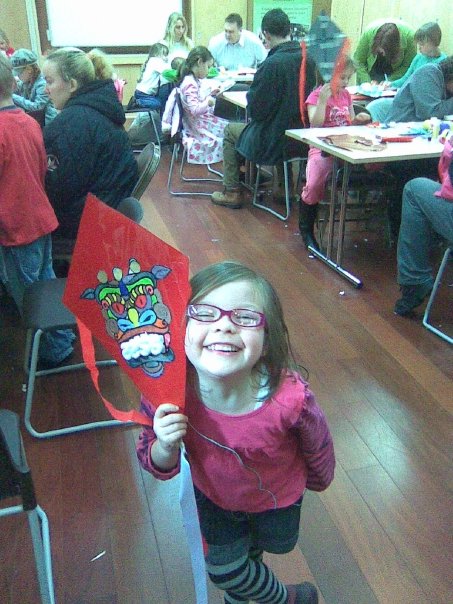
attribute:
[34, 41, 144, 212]
woman — in a black jacket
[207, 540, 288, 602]
girl — wearing striped pants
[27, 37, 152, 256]
person — sitting down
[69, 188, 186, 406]
kite — red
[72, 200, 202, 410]
kite — red, small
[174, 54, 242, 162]
girl — little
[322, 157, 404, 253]
girl — little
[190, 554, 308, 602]
leggings — striped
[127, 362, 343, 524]
shirt — pink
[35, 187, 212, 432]
kite — red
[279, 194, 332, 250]
boots — black, tall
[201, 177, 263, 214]
boot — brown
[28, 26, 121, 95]
hair — pony tail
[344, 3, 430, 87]
shirt — bright green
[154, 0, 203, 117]
hair — long, blonde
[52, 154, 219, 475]
kite — red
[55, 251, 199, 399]
face — monster looking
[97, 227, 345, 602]
child — small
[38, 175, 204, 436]
kite — red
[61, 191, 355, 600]
girl — little, smiling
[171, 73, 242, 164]
dress — floral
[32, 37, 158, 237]
woman — sitting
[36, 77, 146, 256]
coat — black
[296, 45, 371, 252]
girl — pink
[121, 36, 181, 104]
girl — little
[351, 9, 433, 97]
jacket — green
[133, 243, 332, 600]
girl — small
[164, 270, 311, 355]
glasses — purple, a pair, framed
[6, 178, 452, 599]
flooring — hardwood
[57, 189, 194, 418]
kite — red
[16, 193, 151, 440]
chair — black, grey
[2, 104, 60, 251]
shirt — red